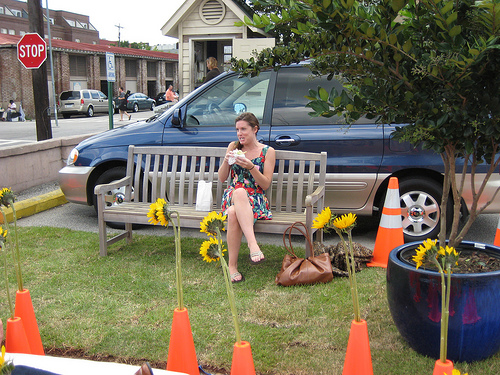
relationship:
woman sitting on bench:
[218, 109, 275, 282] [94, 145, 333, 257]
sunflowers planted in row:
[157, 204, 366, 252] [8, 334, 460, 375]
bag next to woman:
[194, 180, 218, 212] [218, 109, 275, 282]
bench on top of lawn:
[94, 145, 333, 257] [58, 257, 167, 330]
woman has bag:
[218, 109, 275, 282] [277, 226, 332, 290]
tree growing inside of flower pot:
[280, 0, 499, 248] [386, 240, 500, 360]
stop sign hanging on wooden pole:
[17, 34, 47, 69] [27, 0, 51, 143]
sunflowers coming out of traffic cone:
[157, 204, 366, 252] [165, 308, 200, 374]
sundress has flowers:
[228, 165, 267, 215] [233, 173, 248, 185]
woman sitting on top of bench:
[218, 109, 275, 282] [94, 145, 333, 257]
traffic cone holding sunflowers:
[165, 308, 200, 374] [157, 204, 366, 252]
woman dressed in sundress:
[218, 109, 275, 282] [228, 165, 267, 215]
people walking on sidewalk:
[117, 87, 177, 104] [127, 115, 146, 122]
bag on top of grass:
[277, 226, 332, 290] [280, 286, 343, 297]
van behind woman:
[69, 66, 500, 177] [218, 109, 275, 282]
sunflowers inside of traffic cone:
[157, 204, 366, 252] [165, 308, 200, 374]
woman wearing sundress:
[218, 109, 275, 282] [228, 165, 267, 215]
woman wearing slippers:
[218, 109, 275, 282] [249, 250, 265, 264]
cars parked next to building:
[60, 86, 169, 107] [8, 28, 167, 85]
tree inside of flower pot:
[280, 0, 499, 248] [386, 240, 500, 360]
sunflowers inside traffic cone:
[157, 204, 366, 252] [165, 308, 200, 374]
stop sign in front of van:
[17, 34, 47, 69] [69, 66, 500, 177]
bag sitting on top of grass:
[277, 226, 332, 290] [280, 286, 343, 297]